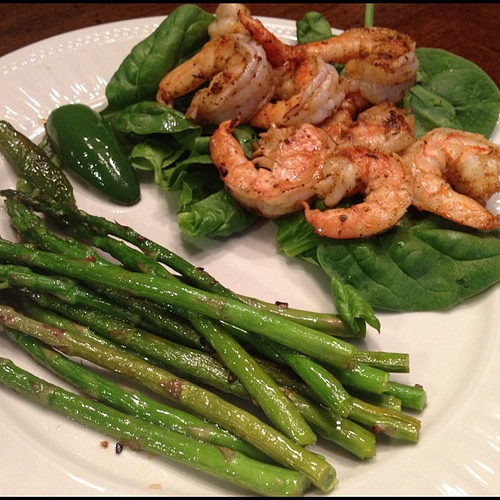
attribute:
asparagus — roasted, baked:
[2, 118, 436, 487]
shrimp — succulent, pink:
[195, 16, 498, 243]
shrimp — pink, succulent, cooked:
[402, 124, 497, 235]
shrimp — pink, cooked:
[298, 144, 411, 239]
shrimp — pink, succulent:
[310, 131, 421, 253]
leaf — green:
[98, 7, 213, 97]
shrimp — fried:
[174, 22, 472, 256]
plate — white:
[9, 13, 111, 101]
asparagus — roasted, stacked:
[0, 168, 436, 488]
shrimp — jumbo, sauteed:
[396, 125, 498, 231]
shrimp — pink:
[221, 89, 403, 209]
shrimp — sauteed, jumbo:
[164, 34, 425, 206]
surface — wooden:
[1, 3, 498, 88]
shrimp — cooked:
[207, 120, 334, 221]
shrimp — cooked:
[250, 51, 345, 126]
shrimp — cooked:
[155, 26, 273, 126]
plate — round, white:
[0, 0, 499, 499]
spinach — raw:
[98, 0, 498, 341]